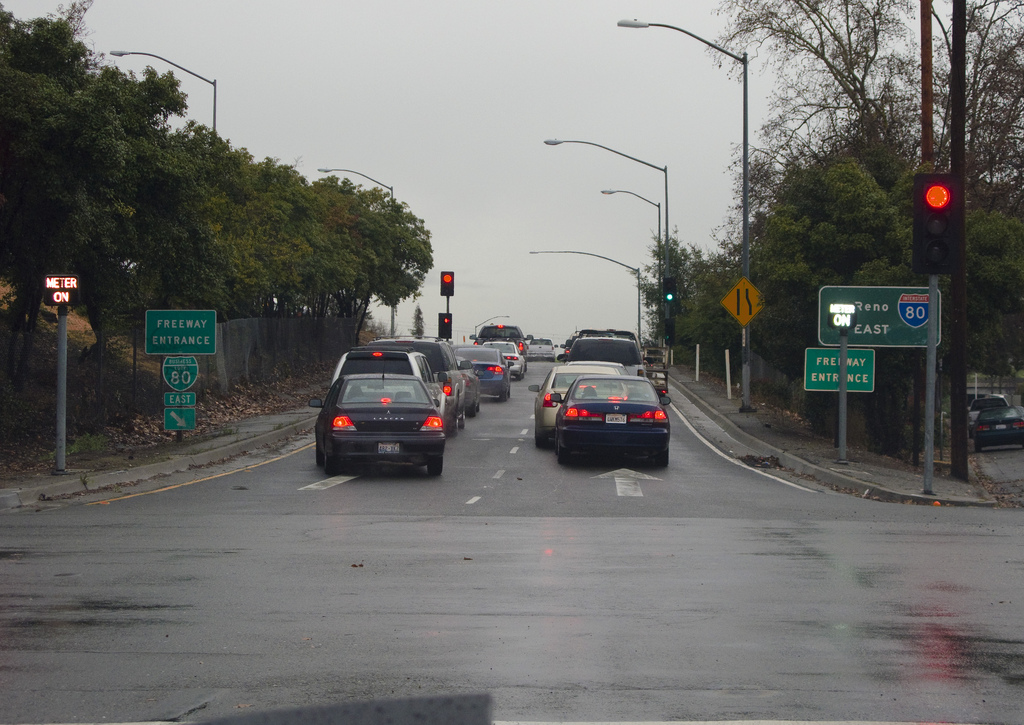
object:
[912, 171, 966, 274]
light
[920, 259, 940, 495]
pole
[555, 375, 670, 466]
car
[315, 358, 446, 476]
car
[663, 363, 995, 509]
curb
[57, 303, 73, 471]
pole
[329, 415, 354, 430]
red light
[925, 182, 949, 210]
street light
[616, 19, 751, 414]
light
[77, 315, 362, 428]
fence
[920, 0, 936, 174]
pole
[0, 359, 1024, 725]
street